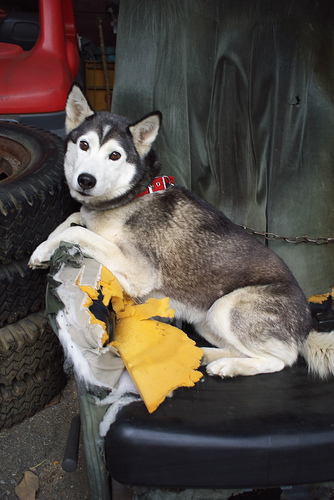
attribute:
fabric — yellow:
[73, 261, 207, 415]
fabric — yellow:
[305, 283, 333, 315]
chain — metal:
[240, 227, 331, 246]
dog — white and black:
[20, 96, 330, 349]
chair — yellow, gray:
[44, 0, 332, 498]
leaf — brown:
[10, 460, 47, 498]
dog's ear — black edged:
[128, 107, 163, 161]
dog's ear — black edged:
[64, 81, 94, 136]